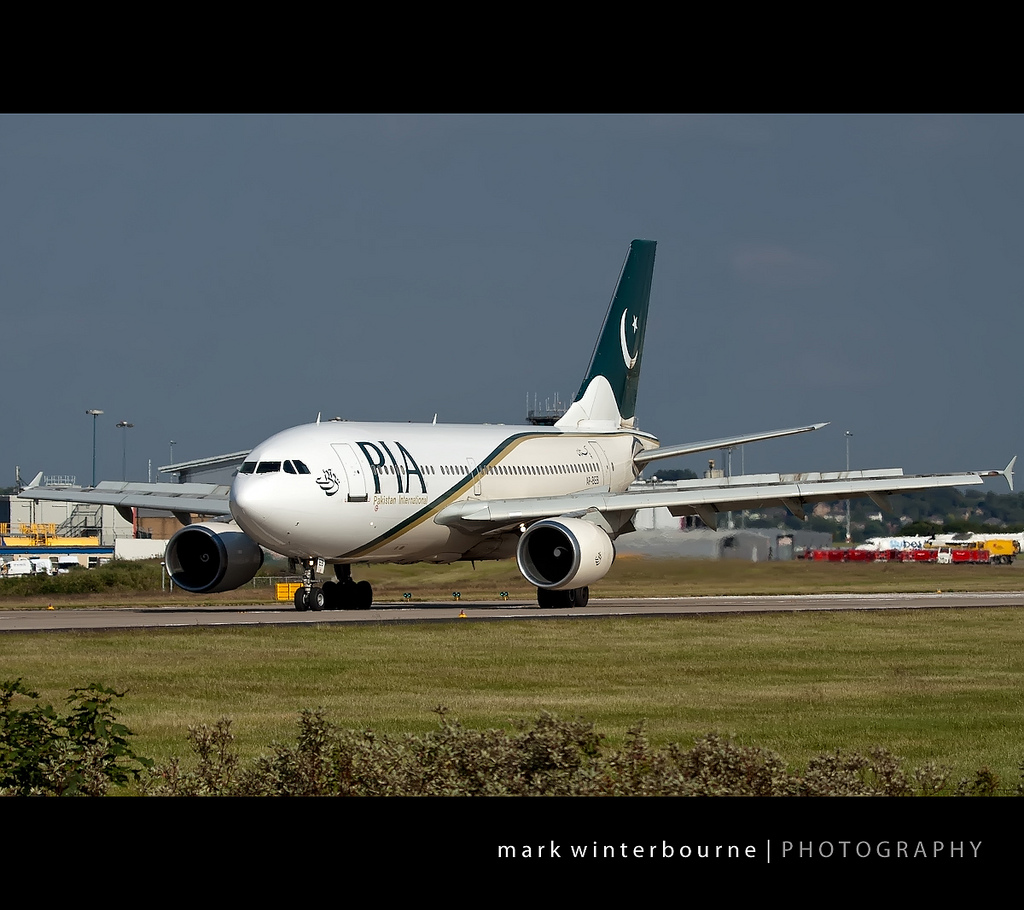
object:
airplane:
[15, 237, 1024, 617]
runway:
[0, 592, 1020, 634]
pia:
[355, 440, 429, 495]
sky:
[0, 110, 1023, 500]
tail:
[554, 239, 657, 427]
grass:
[0, 604, 1024, 800]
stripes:
[335, 432, 661, 558]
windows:
[549, 464, 555, 475]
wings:
[434, 473, 980, 520]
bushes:
[39, 663, 155, 797]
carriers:
[938, 546, 990, 566]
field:
[0, 556, 1019, 614]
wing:
[18, 473, 230, 519]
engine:
[514, 514, 617, 593]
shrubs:
[62, 562, 95, 597]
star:
[631, 315, 638, 334]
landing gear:
[294, 587, 326, 612]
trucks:
[922, 540, 1020, 564]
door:
[329, 442, 369, 502]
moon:
[620, 308, 639, 370]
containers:
[813, 548, 843, 562]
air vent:
[613, 466, 904, 492]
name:
[496, 839, 984, 859]